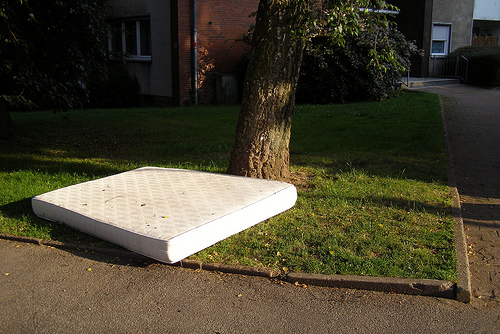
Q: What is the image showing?
A: It is showing a road.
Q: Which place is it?
A: It is a road.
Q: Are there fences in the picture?
A: No, there are no fences.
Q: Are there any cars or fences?
A: No, there are no fences or cars.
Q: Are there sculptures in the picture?
A: No, there are no sculptures.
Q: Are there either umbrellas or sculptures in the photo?
A: No, there are no sculptures or umbrellas.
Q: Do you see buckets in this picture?
A: No, there are no buckets.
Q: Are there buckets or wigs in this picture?
A: No, there are no buckets or wigs.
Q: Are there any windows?
A: Yes, there is a window.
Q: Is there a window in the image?
A: Yes, there is a window.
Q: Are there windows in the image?
A: Yes, there is a window.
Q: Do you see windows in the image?
A: Yes, there is a window.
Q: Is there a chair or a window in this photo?
A: Yes, there is a window.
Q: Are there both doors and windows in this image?
A: No, there is a window but no doors.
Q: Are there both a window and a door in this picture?
A: No, there is a window but no doors.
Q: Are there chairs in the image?
A: No, there are no chairs.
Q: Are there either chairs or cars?
A: No, there are no chairs or cars.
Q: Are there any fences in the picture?
A: No, there are no fences.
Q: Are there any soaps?
A: No, there are no soaps.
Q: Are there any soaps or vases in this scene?
A: No, there are no soaps or vases.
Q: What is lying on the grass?
A: The mattress is lying on the grass.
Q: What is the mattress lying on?
A: The mattress is lying on the grass.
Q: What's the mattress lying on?
A: The mattress is lying on the grass.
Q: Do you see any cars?
A: No, there are no cars.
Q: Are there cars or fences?
A: No, there are no cars or fences.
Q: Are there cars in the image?
A: No, there are no cars.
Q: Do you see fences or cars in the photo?
A: No, there are no cars or fences.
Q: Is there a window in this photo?
A: Yes, there is a window.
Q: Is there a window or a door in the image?
A: Yes, there is a window.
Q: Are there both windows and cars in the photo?
A: No, there is a window but no cars.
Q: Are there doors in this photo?
A: No, there are no doors.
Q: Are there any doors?
A: No, there are no doors.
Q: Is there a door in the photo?
A: No, there are no doors.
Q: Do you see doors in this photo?
A: No, there are no doors.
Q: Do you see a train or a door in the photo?
A: No, there are no doors or trains.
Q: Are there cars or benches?
A: No, there are no cars or benches.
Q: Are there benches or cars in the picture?
A: No, there are no cars or benches.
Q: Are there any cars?
A: No, there are no cars.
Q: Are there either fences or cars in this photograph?
A: No, there are no cars or fences.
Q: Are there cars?
A: No, there are no cars.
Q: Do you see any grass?
A: Yes, there is grass.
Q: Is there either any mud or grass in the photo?
A: Yes, there is grass.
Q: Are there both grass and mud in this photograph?
A: No, there is grass but no mud.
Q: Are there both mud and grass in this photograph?
A: No, there is grass but no mud.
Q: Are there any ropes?
A: No, there are no ropes.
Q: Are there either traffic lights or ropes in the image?
A: No, there are no ropes or traffic lights.